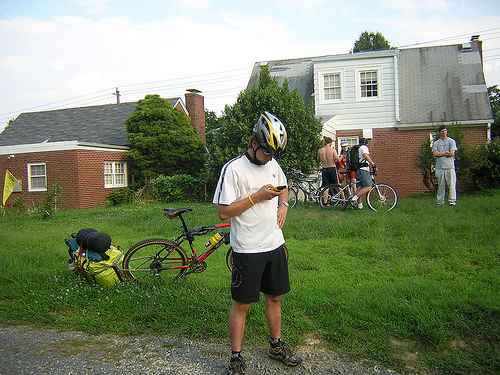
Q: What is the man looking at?
A: Cell phone.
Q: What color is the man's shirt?
A: White.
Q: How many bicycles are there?
A: Three.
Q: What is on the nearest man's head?
A: A helmet.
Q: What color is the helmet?
A: Silver and yellow.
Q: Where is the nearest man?
A: On the gravel.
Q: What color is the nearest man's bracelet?
A: Yellow.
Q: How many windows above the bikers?
A: 2.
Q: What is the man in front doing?
A: Texting.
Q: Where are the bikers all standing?
A: Backyard.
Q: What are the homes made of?
A: Brick.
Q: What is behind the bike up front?
A: Backpack.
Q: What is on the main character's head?
A: Helmet.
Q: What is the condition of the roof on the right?
A: Dirty.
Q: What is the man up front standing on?
A: Gravel.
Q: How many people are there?
A: 5.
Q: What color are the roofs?
A: Gray.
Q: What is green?
A: The tree.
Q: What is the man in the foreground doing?
A: Checking his phone.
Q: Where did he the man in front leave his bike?
A: In the grass.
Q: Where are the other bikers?
A: By the house.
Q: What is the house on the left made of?
A: Brick.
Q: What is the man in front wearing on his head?
A: A helmet.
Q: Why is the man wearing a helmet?
A: To protect his head if he falls.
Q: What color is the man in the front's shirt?
A: White.